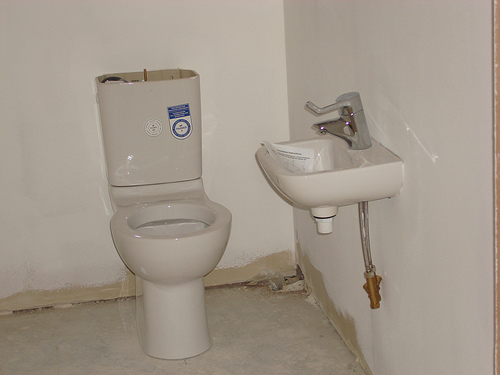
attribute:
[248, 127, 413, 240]
sink — white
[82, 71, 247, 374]
toilet — white, narrow, open, empty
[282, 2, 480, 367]
wall — white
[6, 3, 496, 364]
walls — white, new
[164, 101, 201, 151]
sticker — blue, white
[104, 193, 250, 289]
toilet bowl — round, white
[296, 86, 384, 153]
faucet — silver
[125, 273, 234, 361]
base — white, large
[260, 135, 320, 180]
paper — white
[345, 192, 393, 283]
pipe — metal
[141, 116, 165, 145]
label — white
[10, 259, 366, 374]
ground — white, dingy